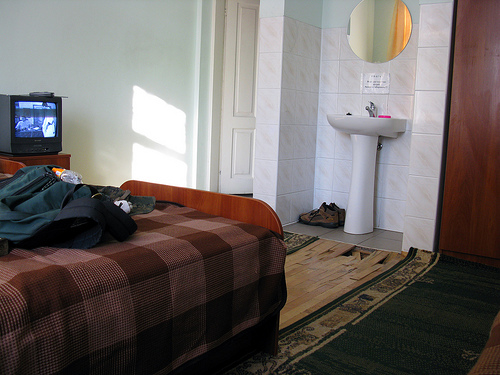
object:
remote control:
[28, 90, 55, 99]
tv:
[0, 85, 70, 157]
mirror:
[339, 0, 412, 65]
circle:
[342, 0, 415, 65]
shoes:
[299, 202, 341, 229]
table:
[0, 149, 72, 169]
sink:
[323, 109, 407, 141]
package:
[51, 166, 84, 186]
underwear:
[51, 166, 84, 186]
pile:
[0, 163, 160, 254]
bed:
[0, 178, 290, 374]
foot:
[0, 169, 18, 178]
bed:
[1, 157, 31, 186]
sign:
[357, 70, 392, 94]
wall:
[252, 0, 454, 251]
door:
[206, 0, 267, 199]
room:
[0, 0, 499, 375]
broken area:
[299, 233, 402, 284]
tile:
[277, 82, 321, 128]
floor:
[225, 209, 500, 375]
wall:
[313, 0, 421, 235]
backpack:
[0, 158, 137, 254]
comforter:
[0, 197, 289, 372]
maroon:
[0, 201, 288, 374]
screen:
[13, 100, 59, 139]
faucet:
[364, 100, 378, 118]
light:
[128, 85, 191, 156]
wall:
[0, 0, 209, 191]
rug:
[203, 230, 499, 373]